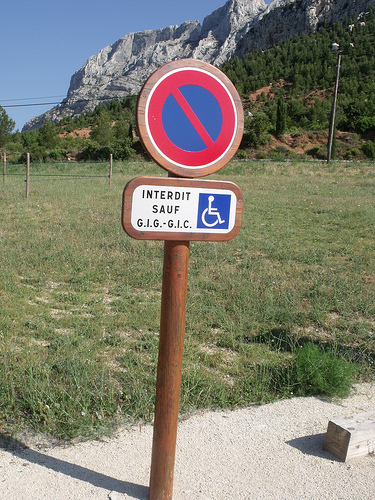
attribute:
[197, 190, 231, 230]
handicap symbol — square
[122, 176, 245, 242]
sign — handicap symbol, handcap symbol, handicap reference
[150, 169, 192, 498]
pole — wooden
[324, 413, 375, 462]
railroad tie — wooden, wood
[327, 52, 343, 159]
telephone pole — tall, distant, leaning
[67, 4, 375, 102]
mountain top — steep, jagged, gray, grey, rocky, white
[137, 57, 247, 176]
sign — round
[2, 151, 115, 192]
fence — wooden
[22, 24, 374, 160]
trees — green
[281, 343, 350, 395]
plants — grassy, green, bushy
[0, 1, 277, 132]
sky — clear, blue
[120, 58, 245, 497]
sign — colorful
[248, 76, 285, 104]
area — sandy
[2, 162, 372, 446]
grass — green grass, patches 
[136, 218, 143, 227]
letter — black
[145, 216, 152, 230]
letter — black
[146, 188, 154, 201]
letter — black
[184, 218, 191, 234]
letter — black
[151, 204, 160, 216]
letter — black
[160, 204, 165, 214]
letter — black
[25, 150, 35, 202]
fence post — wood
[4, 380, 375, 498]
gravel — white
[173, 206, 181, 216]
letter — black